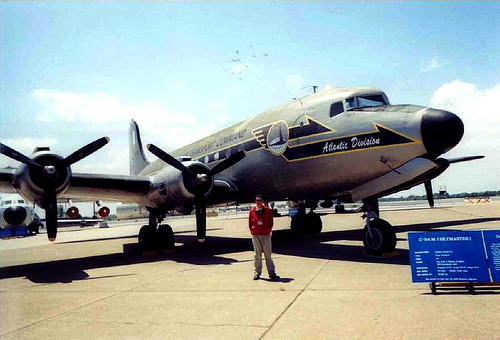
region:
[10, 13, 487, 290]
a man in front of an airplane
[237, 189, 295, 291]
a man wearing a red jacket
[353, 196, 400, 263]
the landing gear of an airplane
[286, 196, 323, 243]
the landing gear of an airplane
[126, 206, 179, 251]
the landing gear of an airplane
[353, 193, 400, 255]
the nose wheel of an airplane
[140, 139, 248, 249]
the propeller of an airplane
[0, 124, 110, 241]
the propeller of an airplane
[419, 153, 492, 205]
the propeller of an airplane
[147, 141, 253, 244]
a large airplane propeller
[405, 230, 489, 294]
a large blue and white sign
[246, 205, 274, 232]
a man's red jacket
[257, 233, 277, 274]
the leg of a man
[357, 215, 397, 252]
a wheel of a plane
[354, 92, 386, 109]
a window of a plane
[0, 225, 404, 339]
part of an airplane tarmac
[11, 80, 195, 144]
a long white cloud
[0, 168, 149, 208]
part of a wing of a plane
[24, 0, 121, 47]
part of a blue sky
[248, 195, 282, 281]
man standing in front of plane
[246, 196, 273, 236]
man wearing red jacket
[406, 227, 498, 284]
blue sign in front of plane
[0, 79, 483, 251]
silver, black and yellow plane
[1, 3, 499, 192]
mostly clear blue sky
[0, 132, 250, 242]
two engines on right wing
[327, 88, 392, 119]
front windshield of plane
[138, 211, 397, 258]
landing gear of the plane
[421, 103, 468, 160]
black nose of plane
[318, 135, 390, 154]
something written in white on the plane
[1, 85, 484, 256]
A grounded silver airplane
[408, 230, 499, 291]
A blue sign with white lettering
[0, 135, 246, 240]
A pair of propellers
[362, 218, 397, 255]
The front wheel of an airplane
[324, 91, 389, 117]
The cockpit of an airplane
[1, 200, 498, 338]
A tarmac made of concrete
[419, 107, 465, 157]
The black nose of an airplane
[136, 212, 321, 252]
The back wheels of an airplane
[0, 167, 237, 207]
The right wing of an airplane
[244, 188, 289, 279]
the man is standing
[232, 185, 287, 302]
the man is standing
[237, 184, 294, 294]
the man is standing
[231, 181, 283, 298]
the man is standing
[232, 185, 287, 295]
the man is standing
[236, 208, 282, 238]
the jacket is red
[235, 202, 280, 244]
the jacket is red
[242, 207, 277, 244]
the jacket is red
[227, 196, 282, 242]
the jacket is red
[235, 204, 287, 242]
the jacket is red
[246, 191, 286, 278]
man standing near the airplane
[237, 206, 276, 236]
man wearing a red jacket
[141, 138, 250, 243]
propellers on the airplane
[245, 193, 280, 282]
man is standing in front of airplane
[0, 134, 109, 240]
airplane jet is on the wing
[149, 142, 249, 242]
airplane jet is on the wing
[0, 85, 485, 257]
airplane is on the runway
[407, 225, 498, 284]
sign is on wheels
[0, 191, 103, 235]
plane is behind planes wing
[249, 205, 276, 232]
coat is red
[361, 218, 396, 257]
wheel is under the plane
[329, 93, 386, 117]
window is in the front of the plane